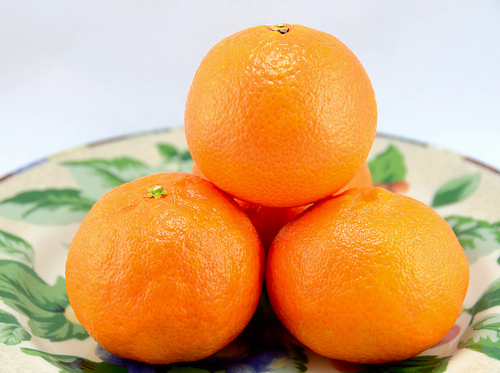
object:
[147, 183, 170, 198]
stem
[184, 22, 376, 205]
fruit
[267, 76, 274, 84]
dimple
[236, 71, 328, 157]
peel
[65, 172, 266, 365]
fruit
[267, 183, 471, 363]
fruit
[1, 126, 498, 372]
plate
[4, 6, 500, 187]
background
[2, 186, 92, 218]
leaf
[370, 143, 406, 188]
leaf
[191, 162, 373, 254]
orange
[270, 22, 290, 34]
nub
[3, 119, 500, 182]
edge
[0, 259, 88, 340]
leaf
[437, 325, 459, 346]
flower